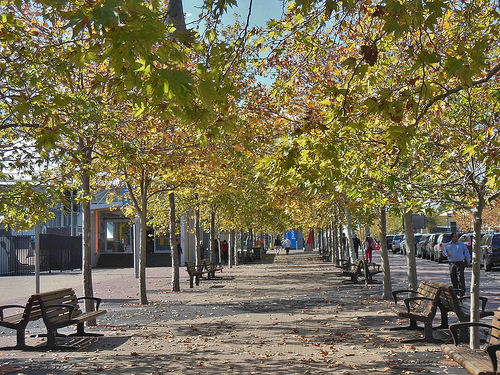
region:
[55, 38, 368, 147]
Leaves are green color.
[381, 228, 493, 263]
Cars are parked in sides of the road.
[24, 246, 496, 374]
Benches are in two sides of the road.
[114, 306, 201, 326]
Road is grey color.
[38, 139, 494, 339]
Trees are on both the sides of the road.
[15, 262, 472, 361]
Shadow falls on road.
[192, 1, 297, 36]
Sky is blue color.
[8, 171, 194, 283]
Building is seen behind the trees.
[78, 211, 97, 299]
Woods are brown color.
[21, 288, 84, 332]
Bench is brown color.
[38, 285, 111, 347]
the tables on the road side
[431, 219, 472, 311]
a man walking on the road side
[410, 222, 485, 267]
the cars parked in the parking area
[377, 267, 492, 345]
two benches attached and arranged on the road side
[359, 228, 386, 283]
an women walking on the road side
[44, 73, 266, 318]
the group of trees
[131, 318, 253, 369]
the leaves fallen from the trees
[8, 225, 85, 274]
the grills used to protect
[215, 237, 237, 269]
the red colored t shirt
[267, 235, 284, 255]
a man with black colored shirt walking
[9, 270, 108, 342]
brown and black benches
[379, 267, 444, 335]
brown and black benches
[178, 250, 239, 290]
brown and black benches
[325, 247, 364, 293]
brown and black bench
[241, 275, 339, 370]
gray pavement covered with leaves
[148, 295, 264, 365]
gray pavement covered with leaves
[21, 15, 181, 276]
trees with brown and green leaves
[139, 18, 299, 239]
trees with brown and green leaves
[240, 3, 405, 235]
trees with brown and green leaves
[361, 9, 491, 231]
trees with brown and green leaves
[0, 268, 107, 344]
back to back benches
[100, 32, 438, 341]
walkway beneath the trees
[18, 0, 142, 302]
skinny tree with green leaves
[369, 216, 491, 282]
cars parked a long the side of a road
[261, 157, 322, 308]
person walking down a path under trees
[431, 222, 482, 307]
man with fancy blue shirt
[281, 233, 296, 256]
distant person wearing black and white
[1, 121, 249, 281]
building behind some trees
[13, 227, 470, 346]
rows of park benches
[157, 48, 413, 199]
leaves on trees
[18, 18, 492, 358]
A sidewalk lined with trees.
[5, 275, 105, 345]
Two benches facing opposite sides.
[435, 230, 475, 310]
A man walking on the sidewalk.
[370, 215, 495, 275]
A long line of cars.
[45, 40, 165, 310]
The trees have slender trunks.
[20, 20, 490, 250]
The leaves are yellow, orange, and light green.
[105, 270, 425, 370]
Dead leaves are all over the sidewalk.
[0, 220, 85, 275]
A tall black metal fence.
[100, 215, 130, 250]
A large glass window.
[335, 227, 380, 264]
A group of people walking next to the trees.